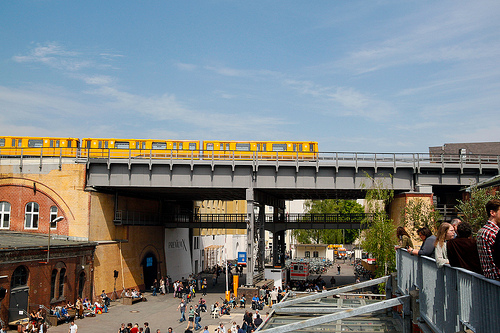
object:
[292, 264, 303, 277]
back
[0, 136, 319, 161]
train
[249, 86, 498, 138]
sky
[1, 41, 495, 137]
clouds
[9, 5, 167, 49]
sky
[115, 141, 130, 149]
window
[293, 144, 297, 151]
window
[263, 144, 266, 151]
window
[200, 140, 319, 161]
cart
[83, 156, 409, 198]
bridge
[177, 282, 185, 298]
people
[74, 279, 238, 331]
pavement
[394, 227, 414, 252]
people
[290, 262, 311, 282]
ambulance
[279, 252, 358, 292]
street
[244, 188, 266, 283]
metal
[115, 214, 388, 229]
walkway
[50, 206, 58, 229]
window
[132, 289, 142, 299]
people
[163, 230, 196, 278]
wall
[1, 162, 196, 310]
building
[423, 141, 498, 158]
building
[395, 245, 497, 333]
fence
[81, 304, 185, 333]
concrete